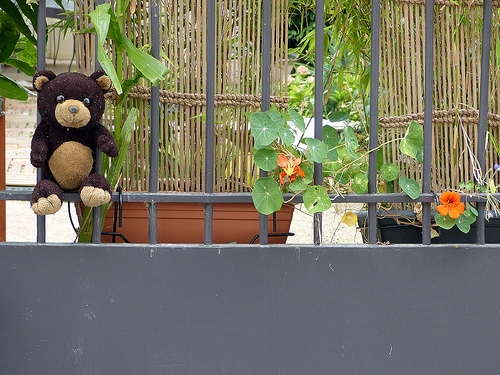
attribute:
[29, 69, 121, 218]
teddy bear — brown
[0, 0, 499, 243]
fence — grey, metal, gray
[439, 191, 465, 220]
flower — orange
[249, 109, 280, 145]
leaf — green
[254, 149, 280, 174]
leaf — green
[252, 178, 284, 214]
leaf — green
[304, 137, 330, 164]
leaf — green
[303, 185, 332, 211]
leaf — green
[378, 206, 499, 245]
flower box — black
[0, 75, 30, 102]
leaf — green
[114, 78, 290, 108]
rope — thick